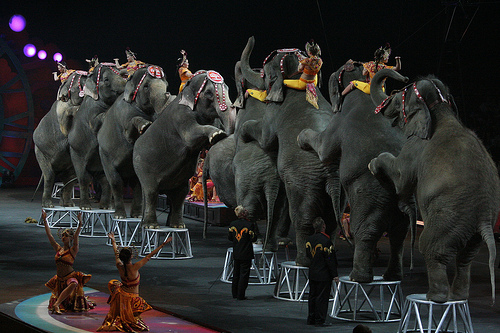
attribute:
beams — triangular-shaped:
[336, 284, 354, 317]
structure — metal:
[330, 275, 405, 323]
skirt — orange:
[107, 289, 142, 315]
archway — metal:
[0, 62, 29, 187]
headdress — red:
[199, 65, 229, 114]